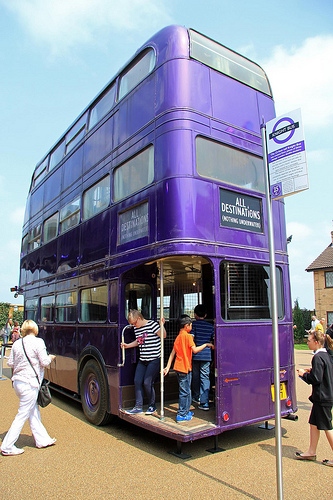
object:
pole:
[261, 127, 283, 499]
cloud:
[6, 0, 170, 52]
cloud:
[306, 146, 332, 165]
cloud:
[286, 218, 333, 312]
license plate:
[270, 380, 288, 403]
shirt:
[6, 334, 53, 390]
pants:
[176, 370, 192, 417]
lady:
[0, 319, 56, 456]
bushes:
[292, 300, 317, 344]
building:
[304, 218, 333, 336]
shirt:
[173, 330, 196, 374]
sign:
[117, 201, 148, 247]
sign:
[266, 107, 310, 200]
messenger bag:
[34, 386, 57, 405]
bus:
[10, 25, 297, 443]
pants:
[134, 359, 161, 406]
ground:
[203, 79, 250, 113]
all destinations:
[220, 188, 263, 233]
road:
[0, 338, 333, 500]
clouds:
[0, 207, 25, 257]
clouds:
[262, 33, 333, 129]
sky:
[0, 1, 333, 313]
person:
[159, 317, 214, 424]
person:
[189, 304, 215, 410]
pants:
[191, 360, 210, 407]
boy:
[160, 314, 215, 423]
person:
[120, 308, 166, 415]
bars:
[168, 435, 226, 459]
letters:
[222, 198, 256, 234]